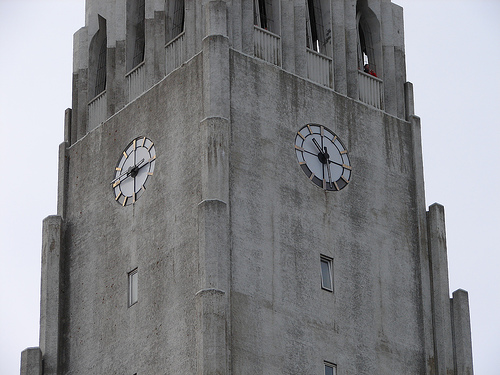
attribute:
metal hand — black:
[126, 158, 153, 181]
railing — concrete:
[160, 34, 190, 61]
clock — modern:
[289, 118, 356, 195]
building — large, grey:
[49, 11, 412, 299]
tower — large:
[50, 19, 459, 367]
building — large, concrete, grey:
[17, 0, 477, 375]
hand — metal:
[131, 155, 147, 170]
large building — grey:
[20, 0, 473, 372]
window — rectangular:
[318, 254, 331, 289]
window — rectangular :
[319, 252, 336, 291]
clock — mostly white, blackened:
[286, 117, 365, 200]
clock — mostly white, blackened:
[98, 132, 166, 211]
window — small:
[315, 251, 342, 296]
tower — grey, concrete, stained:
[38, 1, 466, 373]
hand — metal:
[108, 169, 127, 187]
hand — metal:
[307, 135, 333, 158]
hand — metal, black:
[321, 146, 333, 182]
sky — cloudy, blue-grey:
[413, 4, 498, 374]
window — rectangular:
[128, 267, 139, 307]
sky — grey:
[0, 2, 78, 307]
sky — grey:
[409, 3, 499, 262]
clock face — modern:
[292, 118, 354, 193]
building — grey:
[70, 5, 438, 374]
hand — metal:
[316, 135, 332, 195]